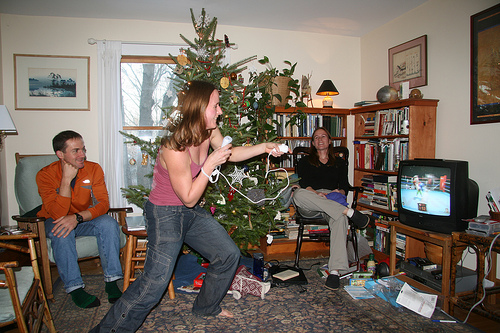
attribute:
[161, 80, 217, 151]
hair — brown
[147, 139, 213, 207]
shirt — pink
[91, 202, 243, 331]
pants — blue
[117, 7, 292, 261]
tree — green, here, large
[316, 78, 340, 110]
lamp — black, here, small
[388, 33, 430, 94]
picture — red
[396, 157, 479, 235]
tv — here, black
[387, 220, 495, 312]
desk — wooden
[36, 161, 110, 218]
shirt — orange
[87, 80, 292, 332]
lady — here, standing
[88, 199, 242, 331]
jean — blue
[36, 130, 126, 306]
man — sitting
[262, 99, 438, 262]
bookcase — here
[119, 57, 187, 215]
window — here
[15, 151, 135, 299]
chair — here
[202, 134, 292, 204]
controller — white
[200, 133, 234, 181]
controller — here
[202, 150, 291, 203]
cord — white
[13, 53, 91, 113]
frame — brown